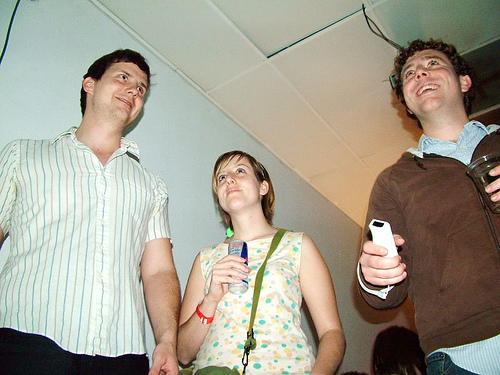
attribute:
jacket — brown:
[366, 159, 499, 288]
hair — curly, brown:
[387, 28, 457, 55]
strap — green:
[246, 240, 294, 272]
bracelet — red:
[190, 293, 218, 325]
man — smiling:
[52, 33, 164, 151]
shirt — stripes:
[9, 120, 162, 359]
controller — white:
[358, 212, 404, 289]